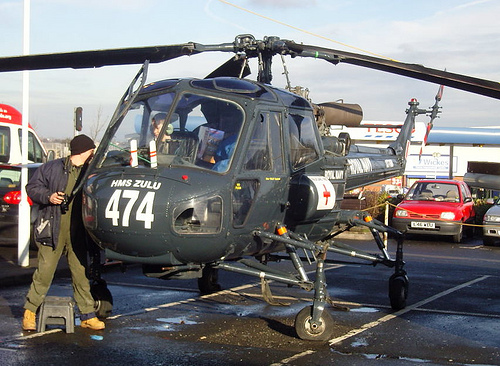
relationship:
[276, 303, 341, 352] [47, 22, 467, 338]
tire of helicopter